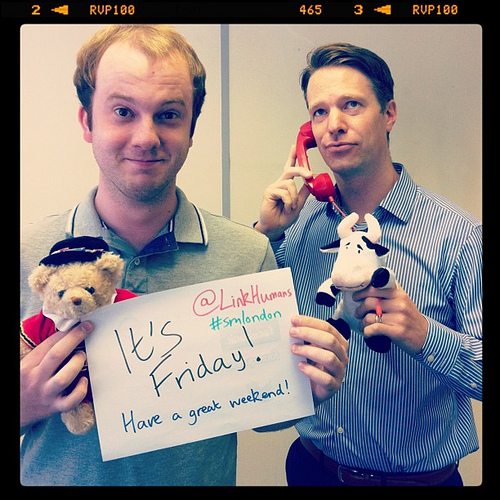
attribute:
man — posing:
[16, 24, 350, 489]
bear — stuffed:
[20, 236, 138, 436]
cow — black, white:
[316, 211, 396, 351]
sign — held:
[82, 266, 316, 463]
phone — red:
[297, 120, 384, 323]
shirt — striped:
[254, 162, 483, 474]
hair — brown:
[301, 42, 394, 144]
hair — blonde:
[72, 24, 206, 137]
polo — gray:
[20, 185, 280, 487]